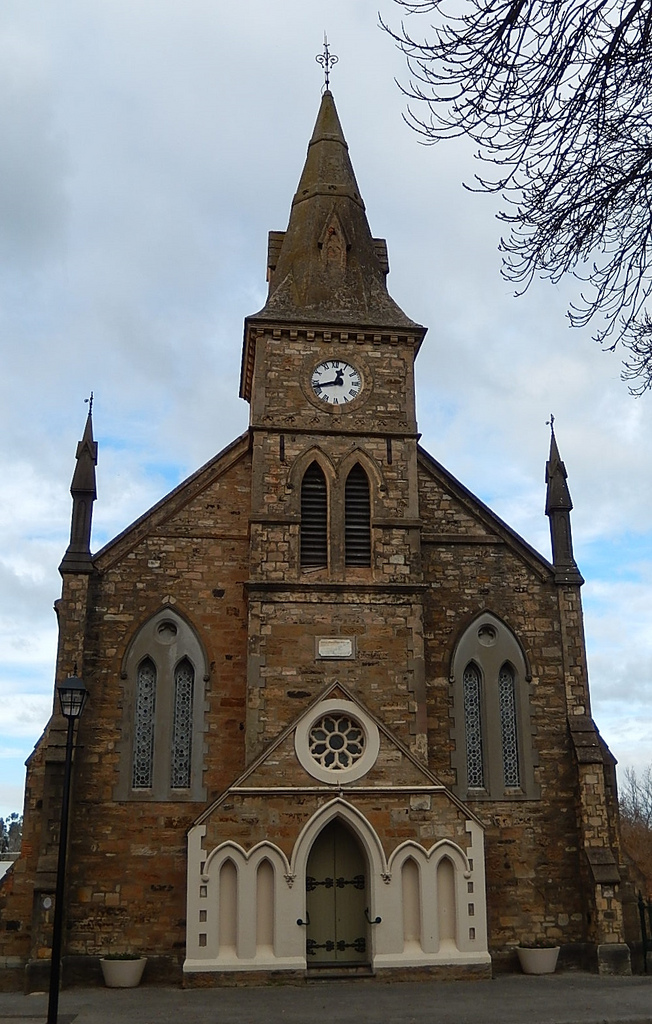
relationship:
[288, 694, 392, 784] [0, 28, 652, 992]
circle on building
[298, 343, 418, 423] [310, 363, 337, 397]
clock with numerals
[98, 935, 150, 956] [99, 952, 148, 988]
plant in fern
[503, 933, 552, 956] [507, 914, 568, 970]
plant in planter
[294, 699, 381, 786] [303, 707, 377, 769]
circle with decoration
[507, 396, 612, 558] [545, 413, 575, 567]
decorative turrent with decorative turrent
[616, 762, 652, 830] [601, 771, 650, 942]
leaves with leaves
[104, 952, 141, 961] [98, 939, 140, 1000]
plant in pot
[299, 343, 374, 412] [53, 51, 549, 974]
clock on church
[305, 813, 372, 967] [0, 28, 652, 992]
door of building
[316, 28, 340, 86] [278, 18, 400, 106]
top on steeple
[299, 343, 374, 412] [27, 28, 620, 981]
clock on building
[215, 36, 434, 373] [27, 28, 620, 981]
steeple on building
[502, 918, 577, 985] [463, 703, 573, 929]
planter beside wall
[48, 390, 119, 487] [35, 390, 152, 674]
top of pole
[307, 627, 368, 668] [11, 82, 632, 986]
plaque on building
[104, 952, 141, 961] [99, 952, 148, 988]
plant in fern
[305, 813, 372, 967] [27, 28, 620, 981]
door to building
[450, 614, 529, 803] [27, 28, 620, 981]
window in building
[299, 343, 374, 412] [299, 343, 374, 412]
clock on clock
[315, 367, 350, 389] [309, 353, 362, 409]
hands on clock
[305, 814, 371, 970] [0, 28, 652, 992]
door at building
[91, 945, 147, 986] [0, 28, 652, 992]
fern in front of building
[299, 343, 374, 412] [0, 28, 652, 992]
clock atop building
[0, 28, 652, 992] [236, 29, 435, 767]
building with tower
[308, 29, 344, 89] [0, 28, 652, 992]
top of building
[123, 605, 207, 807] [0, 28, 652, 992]
window of building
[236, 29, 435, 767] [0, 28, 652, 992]
tower of building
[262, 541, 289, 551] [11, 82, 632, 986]
brick on building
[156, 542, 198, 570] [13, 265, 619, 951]
brick on building